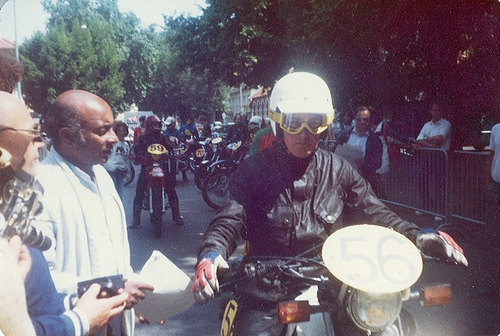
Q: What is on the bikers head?
A: A helmet.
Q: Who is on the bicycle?
A: A man.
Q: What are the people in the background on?
A: Bikes.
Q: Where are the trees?
A: Against the skyline.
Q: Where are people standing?
A: Behind a fence.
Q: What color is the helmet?
A: White.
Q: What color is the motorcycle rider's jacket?
A: Black.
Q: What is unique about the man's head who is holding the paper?
A: He is bald.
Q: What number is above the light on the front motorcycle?
A: 56.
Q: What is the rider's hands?
A: Gloves.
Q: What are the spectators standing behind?
A: Metal barricades.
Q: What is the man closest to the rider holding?
A: Paper.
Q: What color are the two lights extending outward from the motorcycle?
A: Orange.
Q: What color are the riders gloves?
A: White, red, and blue.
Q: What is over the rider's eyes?
A: Goggles.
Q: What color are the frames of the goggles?
A: Yellow.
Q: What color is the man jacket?
A: Black.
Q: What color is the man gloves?
A: Red, white and blue.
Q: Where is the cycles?
A: In the shade.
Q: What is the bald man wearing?
A: Light colored long sleeve jacket.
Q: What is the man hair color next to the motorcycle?
A: He's bald.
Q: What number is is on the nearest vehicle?
A: 56.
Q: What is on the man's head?
A: A helmet.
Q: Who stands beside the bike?
A: A bald man.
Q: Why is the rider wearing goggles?
A: Eye protection.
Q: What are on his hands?
A: Gloves.